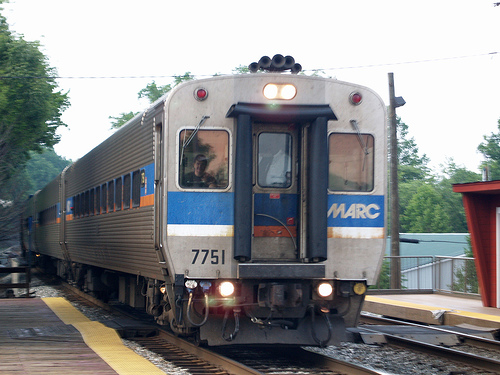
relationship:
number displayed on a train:
[188, 247, 226, 266] [23, 54, 390, 347]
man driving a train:
[181, 154, 216, 188] [23, 54, 390, 347]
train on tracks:
[23, 54, 390, 347] [28, 261, 485, 366]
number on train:
[192, 249, 200, 265] [23, 54, 390, 347]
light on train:
[218, 281, 235, 298] [74, 41, 404, 358]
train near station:
[23, 54, 390, 347] [2, 177, 499, 367]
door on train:
[240, 116, 312, 258] [23, 54, 390, 347]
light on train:
[264, 82, 296, 101] [23, 54, 390, 347]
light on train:
[219, 277, 236, 299] [23, 54, 390, 347]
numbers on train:
[190, 246, 225, 266] [23, 54, 390, 347]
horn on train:
[244, 51, 308, 73] [146, 60, 413, 350]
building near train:
[445, 167, 497, 322] [21, 73, 411, 362]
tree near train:
[3, 1, 86, 215] [23, 54, 390, 347]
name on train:
[327, 196, 382, 228] [23, 54, 390, 347]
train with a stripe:
[23, 54, 390, 347] [165, 192, 385, 237]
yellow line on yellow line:
[38, 293, 176, 374] [368, 293, 499, 325]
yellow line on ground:
[38, 293, 176, 374] [27, 288, 116, 365]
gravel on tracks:
[131, 305, 498, 371] [107, 283, 498, 371]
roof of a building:
[378, 217, 487, 264] [401, 228, 469, 291]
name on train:
[327, 203, 382, 219] [153, 67, 393, 347]